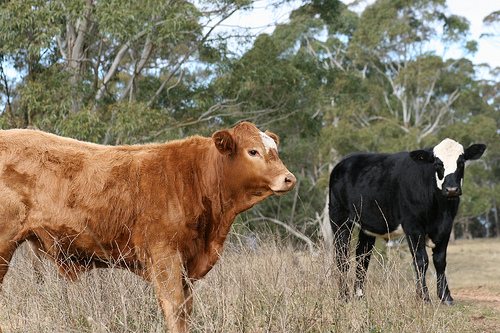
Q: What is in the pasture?
A: Cows.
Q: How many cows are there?
A: Two.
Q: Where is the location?
A: A pasture.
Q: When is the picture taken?
A: Daytime.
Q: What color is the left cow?
A: Brown.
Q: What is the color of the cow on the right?
A: Black and white.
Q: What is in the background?
A: Trees.